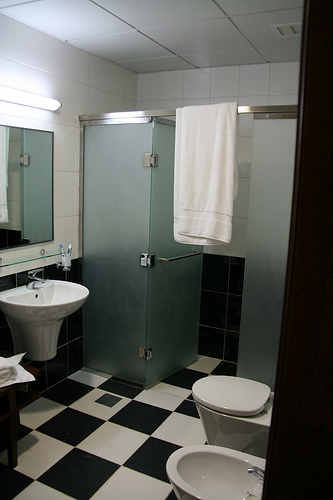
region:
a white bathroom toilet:
[193, 354, 274, 455]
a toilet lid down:
[175, 356, 301, 470]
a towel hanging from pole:
[171, 86, 269, 269]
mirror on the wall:
[10, 121, 82, 255]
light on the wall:
[3, 68, 67, 125]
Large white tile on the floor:
[180, 347, 220, 370]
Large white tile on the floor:
[147, 410, 210, 453]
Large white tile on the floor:
[66, 380, 124, 421]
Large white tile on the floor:
[73, 427, 148, 458]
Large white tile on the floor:
[19, 401, 67, 421]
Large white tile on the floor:
[2, 437, 69, 473]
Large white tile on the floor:
[73, 466, 170, 499]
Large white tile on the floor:
[6, 477, 64, 498]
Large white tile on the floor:
[71, 367, 110, 384]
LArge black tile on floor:
[46, 375, 85, 403]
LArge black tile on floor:
[207, 353, 239, 379]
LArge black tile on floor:
[149, 361, 207, 390]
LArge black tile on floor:
[169, 390, 199, 419]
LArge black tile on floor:
[105, 402, 175, 431]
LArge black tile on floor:
[95, 369, 144, 402]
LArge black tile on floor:
[31, 402, 104, 446]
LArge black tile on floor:
[119, 442, 182, 486]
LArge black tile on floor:
[31, 447, 117, 499]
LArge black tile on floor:
[1, 461, 33, 498]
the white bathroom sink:
[0, 276, 89, 361]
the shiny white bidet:
[165, 443, 266, 498]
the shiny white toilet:
[191, 375, 273, 459]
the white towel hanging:
[174, 101, 239, 244]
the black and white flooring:
[1, 353, 236, 498]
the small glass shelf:
[0, 248, 65, 270]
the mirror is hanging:
[0, 123, 55, 250]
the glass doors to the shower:
[78, 105, 299, 389]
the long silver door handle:
[159, 250, 202, 262]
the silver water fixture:
[26, 268, 45, 288]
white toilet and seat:
[191, 373, 275, 460]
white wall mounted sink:
[1, 266, 89, 362]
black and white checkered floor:
[2, 353, 237, 499]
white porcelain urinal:
[165, 444, 265, 499]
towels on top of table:
[1, 349, 40, 470]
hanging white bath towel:
[166, 98, 243, 245]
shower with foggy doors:
[79, 101, 298, 398]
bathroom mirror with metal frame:
[0, 124, 56, 253]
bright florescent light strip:
[0, 82, 62, 113]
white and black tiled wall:
[0, 11, 137, 393]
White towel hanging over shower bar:
[173, 101, 232, 246]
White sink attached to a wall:
[0, 277, 88, 360]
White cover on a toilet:
[193, 374, 268, 416]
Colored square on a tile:
[97, 390, 120, 408]